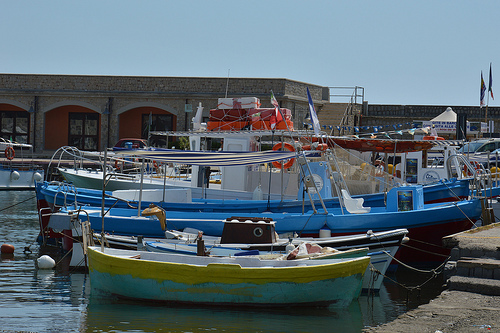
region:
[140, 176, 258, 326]
this is a harbor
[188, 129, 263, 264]
these are some boats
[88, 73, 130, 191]
this is a building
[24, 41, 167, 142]
the building is brick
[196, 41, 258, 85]
there are no clouds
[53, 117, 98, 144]
this is a window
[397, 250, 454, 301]
this is a rope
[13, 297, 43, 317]
this is ocean water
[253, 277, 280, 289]
this is a blue and yellow boat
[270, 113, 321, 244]
the boat is very blue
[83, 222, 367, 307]
a small blue and yellow boar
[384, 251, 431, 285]
rope tethering the boats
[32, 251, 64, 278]
a white floatie in the water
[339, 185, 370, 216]
a white plastic boat seat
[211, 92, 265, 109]
a white box tied to the roof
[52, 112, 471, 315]
colorful boats parked at a marina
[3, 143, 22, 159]
a red lifebuoy on a boat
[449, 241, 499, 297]
stone steps on the dock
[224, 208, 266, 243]
a small brown box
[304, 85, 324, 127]
blue and white flag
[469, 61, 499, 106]
Two flags on poles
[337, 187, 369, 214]
White chair on blue boat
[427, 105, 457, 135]
White tent in back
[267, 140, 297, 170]
Orange life preserver hanging on wall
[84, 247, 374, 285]
Yellow trim on white boat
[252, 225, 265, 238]
Small round window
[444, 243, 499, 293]
Three stairs on concrete walkway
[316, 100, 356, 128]
Stairs leading to top of building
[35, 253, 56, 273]
White buoy floating on water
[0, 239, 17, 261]
Red buoy floating on water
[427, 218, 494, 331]
these are some stairs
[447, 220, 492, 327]
the stairs are stone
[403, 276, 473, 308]
the stones are light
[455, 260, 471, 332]
the stones are old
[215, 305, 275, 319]
the boats are old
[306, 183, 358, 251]
the boat is blue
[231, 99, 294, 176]
this is an orange ring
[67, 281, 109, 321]
this is ocean water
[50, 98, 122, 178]
this is a window